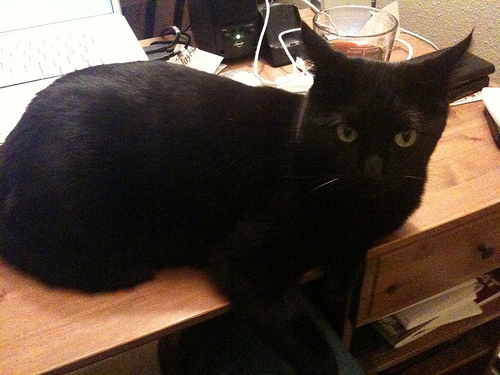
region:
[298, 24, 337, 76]
The left ear of the cat.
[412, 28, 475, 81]
The right ear of the cat.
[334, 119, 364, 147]
The left eye of the cat.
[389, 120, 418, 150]
The right eye of the cat.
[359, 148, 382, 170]
The nose of the cat.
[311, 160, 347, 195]
The whiskers on the left side of the cat's face.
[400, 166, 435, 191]
The whiskers on the right side of the cat's face.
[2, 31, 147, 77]
The keyboard buttons to the laptop behind the cat.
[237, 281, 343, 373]
The cat's left leg.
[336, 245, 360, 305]
The cat's right paw hanging off of the desk.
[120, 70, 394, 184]
this is a cat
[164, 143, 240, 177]
the cat is black in color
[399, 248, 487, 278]
this is a drawer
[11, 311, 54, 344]
this is a table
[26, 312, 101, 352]
the table is brown in color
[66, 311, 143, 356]
the table is wooden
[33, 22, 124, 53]
this is a laptop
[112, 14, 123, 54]
the laptop is white in color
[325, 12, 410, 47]
this is a glass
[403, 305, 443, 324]
this is a book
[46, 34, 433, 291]
The cat is black.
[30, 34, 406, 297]
The cat is laying.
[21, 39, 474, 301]
The cat is on the desk.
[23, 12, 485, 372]
The cat's paws are hanging off.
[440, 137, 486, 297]
The desk is wooden.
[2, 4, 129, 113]
The computer is silver.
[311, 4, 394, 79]
The glass is clear.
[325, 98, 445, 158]
His eyes are black and yellow.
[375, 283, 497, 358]
Paper is hanging out of the drawer.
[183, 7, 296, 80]
The speakers are black.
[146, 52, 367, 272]
the cat is black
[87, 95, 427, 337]
the cat is black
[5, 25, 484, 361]
a black cat on a desk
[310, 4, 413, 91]
a glass on a desk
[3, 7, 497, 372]
a brown wooden desk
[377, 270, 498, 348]
booklets stacked on a desk shelf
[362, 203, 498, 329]
a desk drawer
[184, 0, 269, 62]
a black speaker on a desk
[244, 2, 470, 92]
a white cord on a desk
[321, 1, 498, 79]
carpet on the floor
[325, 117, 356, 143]
a green cat eye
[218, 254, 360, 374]
a cat leg reaching out